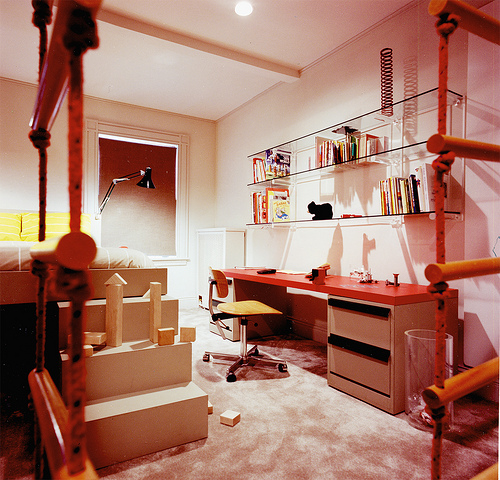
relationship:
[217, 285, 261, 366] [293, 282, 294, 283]
chair by desk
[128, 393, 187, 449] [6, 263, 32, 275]
steps for bed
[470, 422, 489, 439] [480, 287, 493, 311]
shadow on wall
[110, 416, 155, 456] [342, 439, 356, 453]
block on floor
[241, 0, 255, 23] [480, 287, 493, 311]
light on wall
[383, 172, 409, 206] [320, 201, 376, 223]
books on shelf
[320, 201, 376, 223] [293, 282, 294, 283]
shelf on desk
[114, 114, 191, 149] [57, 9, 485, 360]
doorway for room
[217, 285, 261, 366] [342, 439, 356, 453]
chair on floor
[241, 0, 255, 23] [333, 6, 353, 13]
light on ceiling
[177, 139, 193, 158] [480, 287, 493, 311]
window on wall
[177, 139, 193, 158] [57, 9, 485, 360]
window in room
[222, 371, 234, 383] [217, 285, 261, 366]
wheel of chair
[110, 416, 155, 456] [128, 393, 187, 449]
block on steps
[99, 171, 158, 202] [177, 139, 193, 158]
lamp on window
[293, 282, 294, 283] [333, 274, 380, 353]
desk has drawers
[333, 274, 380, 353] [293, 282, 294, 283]
drawers on desk